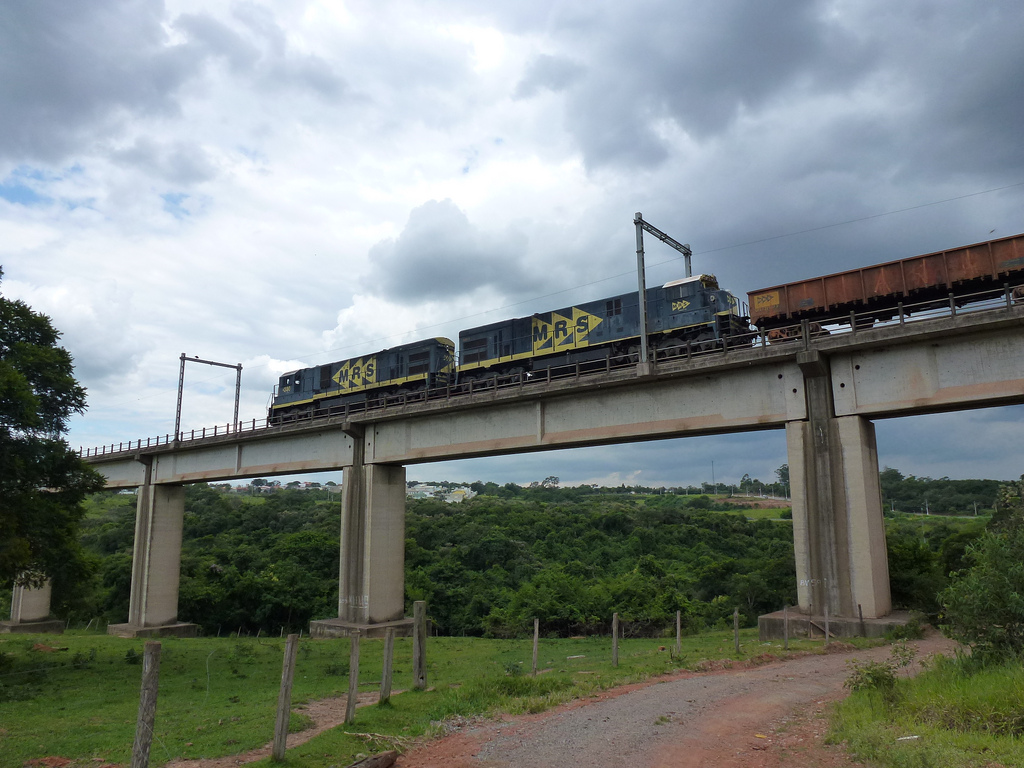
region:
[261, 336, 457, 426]
A diesel engine on a bridge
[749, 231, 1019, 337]
A freight car on a bridge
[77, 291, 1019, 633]
A bridge over a road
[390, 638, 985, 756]
A dirt road under a bridge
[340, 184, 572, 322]
A dark cloud in the sky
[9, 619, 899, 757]
Green grass under a bridge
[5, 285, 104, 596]
A green tree near a bridge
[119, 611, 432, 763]
Fence posts near a bridge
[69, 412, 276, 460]
Guard rails on a bridge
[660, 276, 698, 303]
Windows on a diesel engine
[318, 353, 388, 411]
Yellow painting on the side of the train.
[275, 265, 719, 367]
Blue train on top of bridge.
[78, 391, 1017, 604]
Bridge going across the grass.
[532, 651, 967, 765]
Grey dirt path in the field.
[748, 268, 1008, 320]
Rusty colored part of the train.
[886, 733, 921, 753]
White piece of trash on the ground.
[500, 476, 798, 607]
Top of a bunch of trees in the field.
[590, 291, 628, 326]
Small window on the back of the train.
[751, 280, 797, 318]
Yellow banner on the side of the train.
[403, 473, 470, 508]
White building in the back of the trees.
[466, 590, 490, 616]
leaves on the tree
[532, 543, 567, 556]
leaves on the tree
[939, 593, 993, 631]
leaves on the tree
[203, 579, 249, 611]
leaves on the tree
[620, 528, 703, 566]
leaves on the tree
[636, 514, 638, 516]
leaves on the tree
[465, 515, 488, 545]
leaves on the tree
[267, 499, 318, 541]
leaves on the tree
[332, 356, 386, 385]
Yellow markings on side of train car.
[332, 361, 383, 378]
Blue letters inside of yellow markings.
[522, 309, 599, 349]
Yellow markings on side of train car.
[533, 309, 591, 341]
Blue letters inside of yellow markings.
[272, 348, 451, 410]
Train car is mostly blue in color.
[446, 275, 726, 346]
Train car is mostly blue in color.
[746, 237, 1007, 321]
Brown train car on track.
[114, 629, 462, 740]
Wood posts sticking out of the grass.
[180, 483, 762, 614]
Green tree tops in distance.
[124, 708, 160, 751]
pole on the fence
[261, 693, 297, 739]
pole on the fence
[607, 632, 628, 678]
pole on the fence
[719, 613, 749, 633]
pole on the fence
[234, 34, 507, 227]
Large body of skies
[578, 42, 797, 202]
Large body of skies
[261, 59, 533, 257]
Large body of skies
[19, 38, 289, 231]
Large body of skies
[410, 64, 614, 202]
Large body of skies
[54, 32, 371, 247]
Large body of skies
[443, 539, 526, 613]
A tree in the woods.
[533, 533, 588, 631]
A tree in the woods.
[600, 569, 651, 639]
A tree in the woods.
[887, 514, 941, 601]
A tree in the woods.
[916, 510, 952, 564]
A tree in the woods.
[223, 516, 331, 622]
A tree in the woods.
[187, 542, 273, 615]
A tree in the woods.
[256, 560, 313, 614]
A tree in the woods.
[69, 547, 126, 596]
A tree in the woods.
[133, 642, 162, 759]
brown wooden fence post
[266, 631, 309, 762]
brown wooden fence post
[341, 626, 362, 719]
brown wooden fence post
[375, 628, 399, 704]
brown wooden fence post